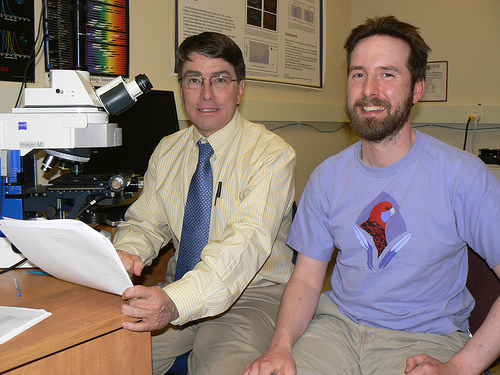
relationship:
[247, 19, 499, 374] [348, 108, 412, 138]
man has beard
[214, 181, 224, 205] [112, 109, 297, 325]
pen in dress shirt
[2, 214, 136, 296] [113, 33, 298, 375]
paper held by man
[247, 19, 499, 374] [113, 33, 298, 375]
man beside man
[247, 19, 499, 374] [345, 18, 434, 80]
man has hair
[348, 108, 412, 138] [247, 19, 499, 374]
beard on man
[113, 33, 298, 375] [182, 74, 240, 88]
man wearing glasses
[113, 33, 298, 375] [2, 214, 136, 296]
man holding paper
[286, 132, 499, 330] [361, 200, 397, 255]
tee shirt has bird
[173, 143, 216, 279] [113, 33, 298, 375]
tie worn by man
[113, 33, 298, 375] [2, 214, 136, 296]
man has paper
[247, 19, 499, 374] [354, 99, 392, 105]
man has mustache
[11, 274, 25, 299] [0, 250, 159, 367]
pen on desk